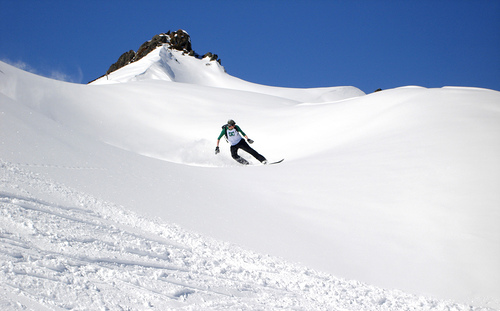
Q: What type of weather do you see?
A: It is clear.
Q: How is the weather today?
A: It is clear.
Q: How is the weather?
A: It is clear.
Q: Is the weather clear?
A: Yes, it is clear.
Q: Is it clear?
A: Yes, it is clear.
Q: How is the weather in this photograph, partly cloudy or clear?
A: It is clear.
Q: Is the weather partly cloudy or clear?
A: It is clear.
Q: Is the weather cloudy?
A: No, it is clear.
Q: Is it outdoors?
A: Yes, it is outdoors.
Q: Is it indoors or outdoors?
A: It is outdoors.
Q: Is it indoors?
A: No, it is outdoors.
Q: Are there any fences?
A: No, there are no fences.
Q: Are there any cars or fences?
A: No, there are no fences or cars.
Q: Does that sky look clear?
A: Yes, the sky is clear.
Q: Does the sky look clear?
A: Yes, the sky is clear.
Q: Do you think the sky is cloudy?
A: No, the sky is clear.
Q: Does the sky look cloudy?
A: No, the sky is clear.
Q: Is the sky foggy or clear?
A: The sky is clear.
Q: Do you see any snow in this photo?
A: Yes, there is snow.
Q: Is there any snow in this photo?
A: Yes, there is snow.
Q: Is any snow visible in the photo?
A: Yes, there is snow.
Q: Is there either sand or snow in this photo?
A: Yes, there is snow.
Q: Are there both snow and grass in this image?
A: No, there is snow but no grass.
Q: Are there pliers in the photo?
A: No, there are no pliers.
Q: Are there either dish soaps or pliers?
A: No, there are no pliers or dish soaps.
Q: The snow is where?
A: The snow is on the ground.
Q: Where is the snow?
A: The snow is on the ground.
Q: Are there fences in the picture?
A: No, there are no fences.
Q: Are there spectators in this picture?
A: No, there are no spectators.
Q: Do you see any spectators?
A: No, there are no spectators.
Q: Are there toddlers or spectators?
A: No, there are no spectators or toddlers.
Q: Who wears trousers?
A: The man wears trousers.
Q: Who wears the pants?
A: The man wears trousers.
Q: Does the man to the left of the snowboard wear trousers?
A: Yes, the man wears trousers.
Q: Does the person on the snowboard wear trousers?
A: Yes, the man wears trousers.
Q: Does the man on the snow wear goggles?
A: No, the man wears trousers.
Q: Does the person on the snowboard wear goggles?
A: No, the man wears trousers.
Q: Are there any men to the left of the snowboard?
A: Yes, there is a man to the left of the snowboard.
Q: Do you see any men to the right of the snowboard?
A: No, the man is to the left of the snowboard.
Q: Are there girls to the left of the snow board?
A: No, there is a man to the left of the snow board.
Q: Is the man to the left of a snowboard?
A: Yes, the man is to the left of a snowboard.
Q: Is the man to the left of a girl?
A: No, the man is to the left of a snowboard.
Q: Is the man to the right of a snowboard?
A: No, the man is to the left of a snowboard.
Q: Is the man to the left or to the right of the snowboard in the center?
A: The man is to the left of the snow board.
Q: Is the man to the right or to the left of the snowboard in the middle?
A: The man is to the left of the snow board.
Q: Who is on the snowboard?
A: The man is on the snowboard.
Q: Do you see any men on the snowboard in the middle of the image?
A: Yes, there is a man on the snowboard.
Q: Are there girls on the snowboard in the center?
A: No, there is a man on the snow board.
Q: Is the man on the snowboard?
A: Yes, the man is on the snowboard.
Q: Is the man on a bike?
A: No, the man is on the snowboard.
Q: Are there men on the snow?
A: Yes, there is a man on the snow.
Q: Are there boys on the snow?
A: No, there is a man on the snow.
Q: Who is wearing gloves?
A: The man is wearing gloves.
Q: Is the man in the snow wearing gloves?
A: Yes, the man is wearing gloves.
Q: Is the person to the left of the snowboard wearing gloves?
A: Yes, the man is wearing gloves.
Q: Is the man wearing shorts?
A: No, the man is wearing gloves.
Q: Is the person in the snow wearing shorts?
A: No, the man is wearing gloves.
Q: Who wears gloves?
A: The man wears gloves.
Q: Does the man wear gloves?
A: Yes, the man wears gloves.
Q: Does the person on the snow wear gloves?
A: Yes, the man wears gloves.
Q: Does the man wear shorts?
A: No, the man wears gloves.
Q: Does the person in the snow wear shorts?
A: No, the man wears gloves.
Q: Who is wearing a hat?
A: The man is wearing a hat.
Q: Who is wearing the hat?
A: The man is wearing a hat.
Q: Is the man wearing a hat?
A: Yes, the man is wearing a hat.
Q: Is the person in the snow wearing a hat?
A: Yes, the man is wearing a hat.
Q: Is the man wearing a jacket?
A: No, the man is wearing a hat.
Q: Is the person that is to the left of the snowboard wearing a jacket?
A: No, the man is wearing a hat.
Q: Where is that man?
A: The man is in the snow.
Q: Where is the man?
A: The man is in the snow.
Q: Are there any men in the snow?
A: Yes, there is a man in the snow.